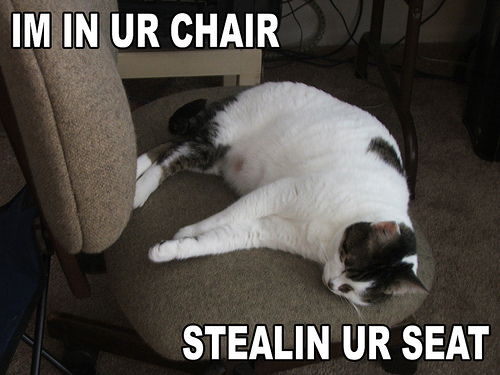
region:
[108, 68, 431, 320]
a cat lying on a chair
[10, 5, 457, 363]
a chair color gray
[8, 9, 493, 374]
white letters on a picture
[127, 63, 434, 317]
cat is brown and white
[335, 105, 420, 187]
black spot on back of cat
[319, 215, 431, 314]
head of cat is brown and white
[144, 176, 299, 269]
front legs of cat are white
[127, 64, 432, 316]
cat is sleeping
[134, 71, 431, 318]
cat is lying on his side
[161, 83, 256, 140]
tail of cat is white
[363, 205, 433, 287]
The ears of the cat.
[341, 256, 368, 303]
The eyes of the cat.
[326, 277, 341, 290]
The nose of the cat.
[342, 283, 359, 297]
The small spot on the cat's face.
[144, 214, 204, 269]
The front paws of the cat.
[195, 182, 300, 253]
The front legs of the cat.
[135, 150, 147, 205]
The back paws of the cat.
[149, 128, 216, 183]
The back legs of the cat.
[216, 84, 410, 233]
The body of the cat.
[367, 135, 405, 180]
The spot on the cat's back.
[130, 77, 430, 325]
White cat with black spots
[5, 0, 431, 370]
grey swivel office chair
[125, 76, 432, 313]
Cat sleeping on chair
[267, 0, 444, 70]
Many different wires going to the table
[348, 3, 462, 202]
Black metallic table legs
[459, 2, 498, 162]
Black desktop computer tower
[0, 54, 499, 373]
Plushy tan carpet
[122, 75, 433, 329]
Cat has long whiskers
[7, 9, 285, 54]
Meme speak lettering over the picture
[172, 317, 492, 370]
Phrase with bad grammar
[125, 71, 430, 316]
a cat lying on chair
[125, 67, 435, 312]
a white and brown cat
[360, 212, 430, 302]
pointy ears of cat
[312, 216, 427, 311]
brown and white head of cat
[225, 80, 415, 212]
body of cat is white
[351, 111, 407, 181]
a black spot on body of cat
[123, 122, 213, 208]
back legs of cat are brown and white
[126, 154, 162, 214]
lower legs of cat are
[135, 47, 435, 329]
cat is taking a nap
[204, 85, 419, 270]
cat has white fur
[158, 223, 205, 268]
cat has white paw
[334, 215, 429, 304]
cat has black ears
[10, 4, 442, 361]
brown chair with cat sleeping on it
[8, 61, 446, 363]
the chair is brown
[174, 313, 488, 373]
the words are white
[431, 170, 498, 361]
the carpet is beinge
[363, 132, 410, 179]
cat has brown spot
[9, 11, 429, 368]
chair sitting on the carpet